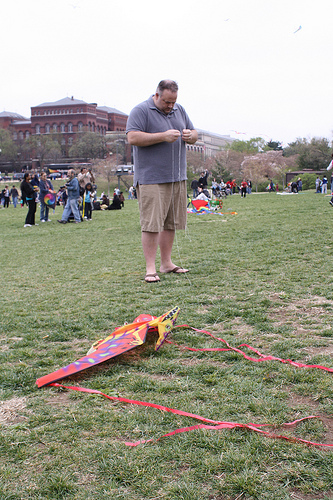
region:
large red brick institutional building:
[0, 96, 269, 171]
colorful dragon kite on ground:
[31, 303, 183, 391]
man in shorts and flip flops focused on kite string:
[126, 78, 201, 283]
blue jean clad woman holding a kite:
[35, 170, 58, 228]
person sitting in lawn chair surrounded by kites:
[187, 183, 218, 218]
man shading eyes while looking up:
[195, 169, 210, 198]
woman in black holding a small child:
[14, 171, 40, 229]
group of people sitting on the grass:
[92, 189, 123, 210]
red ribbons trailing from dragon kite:
[56, 321, 330, 470]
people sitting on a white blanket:
[276, 180, 298, 197]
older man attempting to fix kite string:
[124, 78, 199, 282]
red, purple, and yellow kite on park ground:
[34, 306, 180, 389]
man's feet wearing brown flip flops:
[142, 263, 190, 282]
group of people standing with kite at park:
[17, 168, 98, 225]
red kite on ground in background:
[190, 198, 209, 213]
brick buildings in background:
[0, 95, 235, 161]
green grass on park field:
[0, 181, 332, 498]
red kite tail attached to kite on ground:
[48, 382, 331, 447]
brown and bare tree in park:
[240, 149, 297, 187]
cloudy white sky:
[0, 1, 332, 147]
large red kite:
[19, 292, 181, 393]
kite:
[26, 315, 171, 382]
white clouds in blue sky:
[12, 61, 39, 113]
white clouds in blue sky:
[85, 66, 113, 101]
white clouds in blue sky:
[204, 77, 237, 129]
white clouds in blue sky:
[252, 38, 271, 95]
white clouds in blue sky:
[222, 43, 255, 99]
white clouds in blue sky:
[241, 19, 294, 81]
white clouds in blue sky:
[192, 30, 237, 102]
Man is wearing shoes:
[142, 264, 189, 284]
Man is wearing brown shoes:
[144, 264, 190, 282]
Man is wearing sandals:
[139, 264, 193, 283]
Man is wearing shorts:
[132, 175, 191, 235]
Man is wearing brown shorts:
[134, 177, 188, 234]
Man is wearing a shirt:
[125, 97, 195, 187]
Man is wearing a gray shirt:
[125, 92, 196, 186]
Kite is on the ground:
[35, 304, 331, 453]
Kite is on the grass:
[33, 306, 331, 454]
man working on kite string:
[123, 70, 206, 285]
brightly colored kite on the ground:
[30, 308, 329, 462]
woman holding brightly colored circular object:
[36, 168, 59, 228]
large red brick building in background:
[1, 86, 128, 160]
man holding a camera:
[75, 162, 101, 192]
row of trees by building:
[4, 131, 122, 165]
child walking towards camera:
[79, 180, 99, 220]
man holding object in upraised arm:
[197, 164, 213, 193]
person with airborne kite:
[228, 123, 257, 203]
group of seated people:
[92, 182, 132, 211]